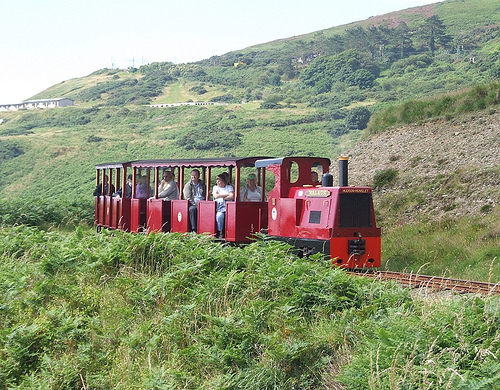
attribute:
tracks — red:
[400, 268, 498, 294]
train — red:
[92, 150, 384, 274]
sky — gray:
[36, 15, 190, 52]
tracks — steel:
[346, 267, 499, 294]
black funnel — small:
[336, 155, 348, 186]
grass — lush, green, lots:
[6, 237, 488, 388]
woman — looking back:
[208, 171, 237, 222]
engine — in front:
[249, 149, 386, 270]